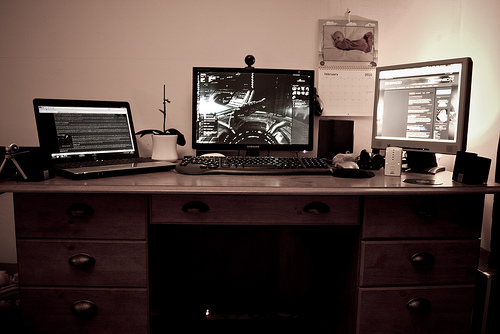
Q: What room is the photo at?
A: It is at the office.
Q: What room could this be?
A: It is an office.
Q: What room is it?
A: It is an office.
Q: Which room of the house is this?
A: It is an office.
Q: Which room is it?
A: It is an office.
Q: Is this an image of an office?
A: Yes, it is showing an office.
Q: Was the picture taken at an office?
A: Yes, it was taken in an office.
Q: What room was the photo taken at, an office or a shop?
A: It was taken at an office.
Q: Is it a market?
A: No, it is an office.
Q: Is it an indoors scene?
A: Yes, it is indoors.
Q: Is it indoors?
A: Yes, it is indoors.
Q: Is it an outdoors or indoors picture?
A: It is indoors.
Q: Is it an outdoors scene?
A: No, it is indoors.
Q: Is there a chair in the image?
A: No, there are no chairs.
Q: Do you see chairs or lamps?
A: No, there are no chairs or lamps.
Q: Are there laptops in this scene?
A: Yes, there is a laptop.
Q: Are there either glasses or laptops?
A: Yes, there is a laptop.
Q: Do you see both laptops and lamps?
A: No, there is a laptop but no lamps.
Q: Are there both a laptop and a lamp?
A: No, there is a laptop but no lamps.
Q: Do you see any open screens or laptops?
A: Yes, there is an open laptop.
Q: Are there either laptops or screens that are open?
A: Yes, the laptop is open.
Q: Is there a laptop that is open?
A: Yes, there is an open laptop.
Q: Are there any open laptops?
A: Yes, there is an open laptop.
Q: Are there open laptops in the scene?
A: Yes, there is an open laptop.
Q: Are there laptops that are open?
A: Yes, there is an open laptop.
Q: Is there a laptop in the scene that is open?
A: Yes, there is a laptop that is open.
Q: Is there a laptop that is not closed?
A: Yes, there is a open laptop.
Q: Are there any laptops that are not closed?
A: Yes, there is a open laptop.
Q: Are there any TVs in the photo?
A: No, there are no tvs.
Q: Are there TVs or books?
A: No, there are no TVs or books.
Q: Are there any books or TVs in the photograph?
A: No, there are no TVs or books.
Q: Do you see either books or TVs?
A: No, there are no TVs or books.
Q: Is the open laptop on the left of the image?
A: Yes, the laptop is on the left of the image.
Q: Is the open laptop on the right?
A: No, the laptop is on the left of the image.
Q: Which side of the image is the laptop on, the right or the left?
A: The laptop is on the left of the image.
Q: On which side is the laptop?
A: The laptop is on the left of the image.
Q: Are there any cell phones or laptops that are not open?
A: No, there is a laptop but it is open.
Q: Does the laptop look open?
A: Yes, the laptop is open.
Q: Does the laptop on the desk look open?
A: Yes, the laptop is open.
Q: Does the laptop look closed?
A: No, the laptop is open.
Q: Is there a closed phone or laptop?
A: No, there is a laptop but it is open.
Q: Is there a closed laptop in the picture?
A: No, there is a laptop but it is open.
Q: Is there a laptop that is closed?
A: No, there is a laptop but it is open.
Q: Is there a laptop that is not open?
A: No, there is a laptop but it is open.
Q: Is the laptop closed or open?
A: The laptop is open.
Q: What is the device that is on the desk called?
A: The device is a laptop.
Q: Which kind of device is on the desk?
A: The device is a laptop.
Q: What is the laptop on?
A: The laptop is on the desk.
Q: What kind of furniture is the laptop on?
A: The laptop is on the desk.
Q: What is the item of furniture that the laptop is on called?
A: The piece of furniture is a desk.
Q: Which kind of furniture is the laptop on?
A: The laptop is on the desk.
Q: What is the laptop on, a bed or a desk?
A: The laptop is on a desk.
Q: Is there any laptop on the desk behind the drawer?
A: Yes, there is a laptop on the desk.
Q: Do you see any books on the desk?
A: No, there is a laptop on the desk.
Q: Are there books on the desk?
A: No, there is a laptop on the desk.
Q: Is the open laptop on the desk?
A: Yes, the laptop is on the desk.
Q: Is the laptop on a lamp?
A: No, the laptop is on the desk.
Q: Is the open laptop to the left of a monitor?
A: Yes, the laptop is to the left of a monitor.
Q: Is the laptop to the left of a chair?
A: No, the laptop is to the left of a monitor.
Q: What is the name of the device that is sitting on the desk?
A: The device is a laptop.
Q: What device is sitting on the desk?
A: The device is a laptop.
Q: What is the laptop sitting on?
A: The laptop is sitting on the desk.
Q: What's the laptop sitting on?
A: The laptop is sitting on the desk.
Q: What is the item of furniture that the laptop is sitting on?
A: The piece of furniture is a desk.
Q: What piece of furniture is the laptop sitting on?
A: The laptop is sitting on the desk.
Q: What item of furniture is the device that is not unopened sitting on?
A: The laptop is sitting on the desk.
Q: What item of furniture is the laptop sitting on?
A: The laptop is sitting on the desk.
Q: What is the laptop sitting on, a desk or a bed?
A: The laptop is sitting on a desk.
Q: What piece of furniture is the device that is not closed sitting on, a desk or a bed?
A: The laptop is sitting on a desk.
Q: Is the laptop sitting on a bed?
A: No, the laptop is sitting on the desk.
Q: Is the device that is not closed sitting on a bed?
A: No, the laptop is sitting on the desk.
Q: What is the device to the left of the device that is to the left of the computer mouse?
A: The device is a laptop.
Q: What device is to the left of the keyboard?
A: The device is a laptop.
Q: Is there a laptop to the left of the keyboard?
A: Yes, there is a laptop to the left of the keyboard.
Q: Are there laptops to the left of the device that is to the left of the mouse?
A: Yes, there is a laptop to the left of the keyboard.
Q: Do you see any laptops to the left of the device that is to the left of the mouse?
A: Yes, there is a laptop to the left of the keyboard.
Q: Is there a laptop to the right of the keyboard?
A: No, the laptop is to the left of the keyboard.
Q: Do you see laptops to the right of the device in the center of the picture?
A: No, the laptop is to the left of the keyboard.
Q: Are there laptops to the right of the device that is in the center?
A: No, the laptop is to the left of the keyboard.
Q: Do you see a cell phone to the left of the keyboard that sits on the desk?
A: No, there is a laptop to the left of the keyboard.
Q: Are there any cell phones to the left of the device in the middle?
A: No, there is a laptop to the left of the keyboard.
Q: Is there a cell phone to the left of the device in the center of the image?
A: No, there is a laptop to the left of the keyboard.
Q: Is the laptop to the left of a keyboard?
A: Yes, the laptop is to the left of a keyboard.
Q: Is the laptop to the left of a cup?
A: No, the laptop is to the left of a keyboard.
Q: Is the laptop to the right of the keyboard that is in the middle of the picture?
A: No, the laptop is to the left of the keyboard.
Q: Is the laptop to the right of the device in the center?
A: No, the laptop is to the left of the keyboard.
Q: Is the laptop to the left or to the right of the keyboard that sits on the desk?
A: The laptop is to the left of the keyboard.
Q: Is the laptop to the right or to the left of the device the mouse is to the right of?
A: The laptop is to the left of the keyboard.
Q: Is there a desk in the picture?
A: Yes, there is a desk.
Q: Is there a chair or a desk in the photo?
A: Yes, there is a desk.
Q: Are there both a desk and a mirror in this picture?
A: No, there is a desk but no mirrors.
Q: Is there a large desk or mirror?
A: Yes, there is a large desk.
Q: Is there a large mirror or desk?
A: Yes, there is a large desk.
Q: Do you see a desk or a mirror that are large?
A: Yes, the desk is large.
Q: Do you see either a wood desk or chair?
A: Yes, there is a wood desk.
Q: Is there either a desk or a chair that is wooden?
A: Yes, the desk is wooden.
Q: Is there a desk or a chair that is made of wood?
A: Yes, the desk is made of wood.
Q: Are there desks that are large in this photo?
A: Yes, there is a large desk.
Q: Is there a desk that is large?
A: Yes, there is a desk that is large.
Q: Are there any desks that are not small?
A: Yes, there is a large desk.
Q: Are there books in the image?
A: No, there are no books.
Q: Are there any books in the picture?
A: No, there are no books.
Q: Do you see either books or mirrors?
A: No, there are no books or mirrors.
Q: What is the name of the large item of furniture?
A: The piece of furniture is a desk.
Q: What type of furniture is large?
A: The furniture is a desk.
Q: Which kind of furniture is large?
A: The furniture is a desk.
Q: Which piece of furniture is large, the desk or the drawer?
A: The desk is large.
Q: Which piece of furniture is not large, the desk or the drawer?
A: The drawer is not large.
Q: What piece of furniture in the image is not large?
A: The piece of furniture is a drawer.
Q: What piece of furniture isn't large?
A: The piece of furniture is a drawer.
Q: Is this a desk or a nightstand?
A: This is a desk.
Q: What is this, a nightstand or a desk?
A: This is a desk.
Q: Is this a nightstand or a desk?
A: This is a desk.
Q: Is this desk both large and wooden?
A: Yes, the desk is large and wooden.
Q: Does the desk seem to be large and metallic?
A: No, the desk is large but wooden.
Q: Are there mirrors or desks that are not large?
A: No, there is a desk but it is large.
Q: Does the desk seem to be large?
A: Yes, the desk is large.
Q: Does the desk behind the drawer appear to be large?
A: Yes, the desk is large.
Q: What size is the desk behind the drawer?
A: The desk is large.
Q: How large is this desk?
A: The desk is large.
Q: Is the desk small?
A: No, the desk is large.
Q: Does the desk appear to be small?
A: No, the desk is large.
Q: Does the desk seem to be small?
A: No, the desk is large.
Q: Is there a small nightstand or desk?
A: No, there is a desk but it is large.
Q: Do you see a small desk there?
A: No, there is a desk but it is large.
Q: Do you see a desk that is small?
A: No, there is a desk but it is large.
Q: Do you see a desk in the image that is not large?
A: No, there is a desk but it is large.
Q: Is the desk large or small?
A: The desk is large.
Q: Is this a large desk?
A: Yes, this is a large desk.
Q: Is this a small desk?
A: No, this is a large desk.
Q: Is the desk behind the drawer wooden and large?
A: Yes, the desk is wooden and large.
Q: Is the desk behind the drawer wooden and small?
A: No, the desk is wooden but large.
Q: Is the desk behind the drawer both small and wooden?
A: No, the desk is wooden but large.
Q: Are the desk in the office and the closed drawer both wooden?
A: Yes, both the desk and the drawer are wooden.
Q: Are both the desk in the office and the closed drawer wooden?
A: Yes, both the desk and the drawer are wooden.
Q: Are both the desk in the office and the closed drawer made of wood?
A: Yes, both the desk and the drawer are made of wood.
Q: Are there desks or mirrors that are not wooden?
A: No, there is a desk but it is wooden.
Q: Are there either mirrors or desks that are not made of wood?
A: No, there is a desk but it is made of wood.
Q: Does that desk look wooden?
A: Yes, the desk is wooden.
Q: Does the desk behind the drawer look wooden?
A: Yes, the desk is wooden.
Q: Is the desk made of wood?
A: Yes, the desk is made of wood.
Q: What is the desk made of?
A: The desk is made of wood.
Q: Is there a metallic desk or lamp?
A: No, there is a desk but it is wooden.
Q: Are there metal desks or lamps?
A: No, there is a desk but it is wooden.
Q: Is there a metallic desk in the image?
A: No, there is a desk but it is wooden.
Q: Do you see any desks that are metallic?
A: No, there is a desk but it is wooden.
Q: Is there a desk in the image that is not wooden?
A: No, there is a desk but it is wooden.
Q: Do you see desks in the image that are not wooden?
A: No, there is a desk but it is wooden.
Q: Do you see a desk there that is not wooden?
A: No, there is a desk but it is wooden.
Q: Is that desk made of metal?
A: No, the desk is made of wood.